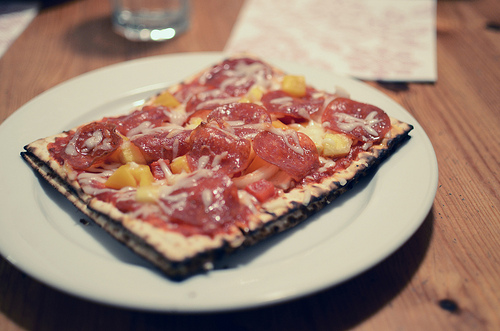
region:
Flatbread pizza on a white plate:
[8, 59, 418, 261]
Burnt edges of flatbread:
[277, 117, 417, 183]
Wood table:
[431, 84, 493, 319]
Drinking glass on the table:
[90, 0, 215, 54]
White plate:
[330, 157, 450, 300]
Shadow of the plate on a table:
[261, 261, 434, 324]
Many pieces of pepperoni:
[131, 102, 328, 177]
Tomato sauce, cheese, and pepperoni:
[87, 119, 193, 211]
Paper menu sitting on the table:
[208, 2, 448, 86]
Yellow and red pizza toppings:
[71, 112, 171, 208]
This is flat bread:
[10, 48, 430, 278]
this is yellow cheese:
[102, 150, 148, 185]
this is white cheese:
[161, 164, 199, 218]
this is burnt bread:
[286, 197, 333, 219]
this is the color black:
[291, 198, 299, 210]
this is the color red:
[208, 136, 220, 145]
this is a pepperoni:
[183, 127, 254, 174]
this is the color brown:
[467, 280, 486, 300]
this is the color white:
[226, 278, 256, 305]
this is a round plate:
[1, 50, 445, 317]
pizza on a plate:
[95, 55, 392, 284]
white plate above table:
[325, 196, 415, 275]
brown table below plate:
[405, 233, 477, 308]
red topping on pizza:
[172, 107, 248, 189]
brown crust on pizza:
[273, 173, 346, 233]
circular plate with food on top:
[310, 178, 405, 290]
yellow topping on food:
[100, 147, 165, 200]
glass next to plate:
[113, 6, 191, 67]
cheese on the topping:
[328, 110, 376, 150]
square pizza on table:
[95, 61, 373, 246]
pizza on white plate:
[1, 50, 448, 312]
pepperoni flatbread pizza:
[48, 50, 238, 245]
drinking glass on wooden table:
[95, 0, 217, 50]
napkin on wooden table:
[225, 0, 457, 85]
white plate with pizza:
[32, 41, 427, 311]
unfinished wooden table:
[411, 46, 496, 326]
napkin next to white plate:
[176, 0, 457, 125]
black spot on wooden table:
[430, 230, 490, 325]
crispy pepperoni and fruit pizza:
[145, 55, 430, 280]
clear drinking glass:
[81, 0, 231, 57]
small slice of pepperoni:
[51, 113, 126, 177]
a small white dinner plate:
[3, 40, 453, 317]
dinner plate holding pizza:
[1, 43, 450, 323]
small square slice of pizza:
[15, 52, 422, 290]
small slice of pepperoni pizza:
[12, 37, 435, 295]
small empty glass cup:
[95, 3, 207, 45]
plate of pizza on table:
[6, 2, 497, 324]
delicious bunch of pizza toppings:
[51, 56, 395, 236]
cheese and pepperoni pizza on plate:
[17, 40, 424, 271]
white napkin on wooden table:
[209, 3, 494, 105]